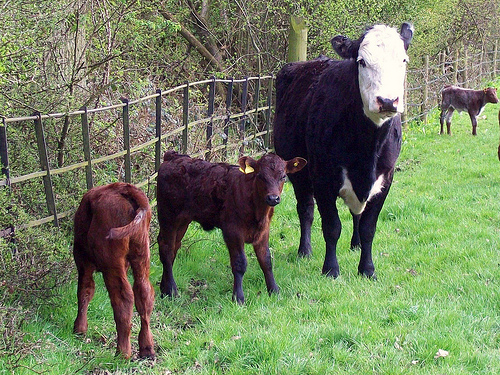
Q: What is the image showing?
A: It is showing a field.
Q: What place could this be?
A: It is a field.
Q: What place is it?
A: It is a field.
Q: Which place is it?
A: It is a field.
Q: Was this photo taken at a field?
A: Yes, it was taken in a field.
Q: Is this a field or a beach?
A: It is a field.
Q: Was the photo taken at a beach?
A: No, the picture was taken in a field.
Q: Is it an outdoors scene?
A: Yes, it is outdoors.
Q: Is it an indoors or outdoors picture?
A: It is outdoors.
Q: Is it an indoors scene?
A: No, it is outdoors.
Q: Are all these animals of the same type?
A: Yes, all the animals are cows.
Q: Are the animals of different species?
A: No, all the animals are cows.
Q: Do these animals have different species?
A: No, all the animals are cows.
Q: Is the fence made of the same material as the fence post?
A: Yes, both the fence and the fence post are made of wood.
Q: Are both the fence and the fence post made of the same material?
A: Yes, both the fence and the fence post are made of wood.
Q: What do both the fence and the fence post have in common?
A: The material, both the fence and the fence post are wooden.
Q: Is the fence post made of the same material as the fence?
A: Yes, both the fence post and the fence are made of wood.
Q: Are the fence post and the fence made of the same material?
A: Yes, both the fence post and the fence are made of wood.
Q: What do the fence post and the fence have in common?
A: The material, both the fence post and the fence are wooden.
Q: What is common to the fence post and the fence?
A: The material, both the fence post and the fence are wooden.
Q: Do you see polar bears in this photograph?
A: No, there are no polar bears.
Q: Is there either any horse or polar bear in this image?
A: No, there are no polar bears or horses.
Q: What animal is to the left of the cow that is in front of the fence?
A: The animal is a calf.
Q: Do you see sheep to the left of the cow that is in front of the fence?
A: No, there is a calf to the left of the cow.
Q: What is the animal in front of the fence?
A: The animal is a calf.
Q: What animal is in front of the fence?
A: The animal is a calf.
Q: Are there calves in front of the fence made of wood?
A: Yes, there is a calf in front of the fence.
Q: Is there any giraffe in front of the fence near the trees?
A: No, there is a calf in front of the fence.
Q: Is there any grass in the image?
A: Yes, there is grass.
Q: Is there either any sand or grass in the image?
A: Yes, there is grass.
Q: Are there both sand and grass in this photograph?
A: No, there is grass but no sand.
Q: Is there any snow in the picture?
A: No, there is no snow.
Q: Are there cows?
A: Yes, there is a cow.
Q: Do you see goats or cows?
A: Yes, there is a cow.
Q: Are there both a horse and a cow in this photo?
A: No, there is a cow but no horses.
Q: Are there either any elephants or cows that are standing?
A: Yes, the cow is standing.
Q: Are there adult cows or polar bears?
A: Yes, there is an adult cow.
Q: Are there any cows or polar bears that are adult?
A: Yes, the cow is adult.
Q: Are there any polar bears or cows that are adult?
A: Yes, the cow is adult.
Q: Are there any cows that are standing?
A: Yes, there is a cow that is standing.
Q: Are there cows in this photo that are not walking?
A: Yes, there is a cow that is standing.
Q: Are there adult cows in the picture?
A: Yes, there is an adult cow.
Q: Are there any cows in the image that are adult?
A: Yes, there is a cow that is adult.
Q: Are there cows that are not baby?
A: Yes, there is a adult cow.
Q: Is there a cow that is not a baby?
A: Yes, there is a adult cow.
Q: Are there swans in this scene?
A: No, there are no swans.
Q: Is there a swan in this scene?
A: No, there are no swans.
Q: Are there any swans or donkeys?
A: No, there are no swans or donkeys.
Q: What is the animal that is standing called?
A: The animal is a cow.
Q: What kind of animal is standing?
A: The animal is a cow.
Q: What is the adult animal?
A: The animal is a cow.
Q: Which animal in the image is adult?
A: The animal is a cow.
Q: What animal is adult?
A: The animal is a cow.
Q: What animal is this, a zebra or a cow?
A: This is a cow.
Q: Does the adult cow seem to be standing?
A: Yes, the cow is standing.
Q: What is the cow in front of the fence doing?
A: The cow is standing.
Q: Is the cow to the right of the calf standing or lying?
A: The cow is standing.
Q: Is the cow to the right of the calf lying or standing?
A: The cow is standing.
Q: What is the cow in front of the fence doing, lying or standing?
A: The cow is standing.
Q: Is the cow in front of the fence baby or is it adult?
A: The cow is adult.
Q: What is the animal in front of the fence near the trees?
A: The animal is a cow.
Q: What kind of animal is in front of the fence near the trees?
A: The animal is a cow.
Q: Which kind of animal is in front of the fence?
A: The animal is a cow.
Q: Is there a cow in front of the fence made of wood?
A: Yes, there is a cow in front of the fence.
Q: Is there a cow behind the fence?
A: No, the cow is in front of the fence.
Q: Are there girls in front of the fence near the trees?
A: No, there is a cow in front of the fence.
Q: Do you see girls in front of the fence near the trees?
A: No, there is a cow in front of the fence.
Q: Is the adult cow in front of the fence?
A: Yes, the cow is in front of the fence.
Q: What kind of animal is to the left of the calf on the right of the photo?
A: The animal is a cow.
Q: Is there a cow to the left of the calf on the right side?
A: Yes, there is a cow to the left of the calf.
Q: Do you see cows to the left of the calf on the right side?
A: Yes, there is a cow to the left of the calf.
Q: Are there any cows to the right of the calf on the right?
A: No, the cow is to the left of the calf.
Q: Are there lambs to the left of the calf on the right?
A: No, there is a cow to the left of the calf.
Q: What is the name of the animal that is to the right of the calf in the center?
A: The animal is a cow.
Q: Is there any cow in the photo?
A: Yes, there is a cow.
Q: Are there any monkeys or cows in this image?
A: Yes, there is a cow.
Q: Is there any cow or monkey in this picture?
A: Yes, there is a cow.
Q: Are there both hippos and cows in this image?
A: No, there is a cow but no hippos.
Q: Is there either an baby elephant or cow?
A: Yes, there is a baby cow.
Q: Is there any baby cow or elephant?
A: Yes, there is a baby cow.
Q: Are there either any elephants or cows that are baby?
A: Yes, the cow is a baby.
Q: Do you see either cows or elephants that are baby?
A: Yes, the cow is a baby.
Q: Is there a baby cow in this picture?
A: Yes, there is a baby cow.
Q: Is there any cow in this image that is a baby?
A: Yes, there is a cow that is a baby.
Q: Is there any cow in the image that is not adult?
A: Yes, there is an baby cow.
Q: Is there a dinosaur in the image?
A: No, there are no dinosaurs.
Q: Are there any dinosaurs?
A: No, there are no dinosaurs.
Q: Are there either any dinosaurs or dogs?
A: No, there are no dinosaurs or dogs.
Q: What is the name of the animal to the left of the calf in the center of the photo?
A: The animal is a cow.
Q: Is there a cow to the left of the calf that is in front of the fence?
A: Yes, there is a cow to the left of the calf.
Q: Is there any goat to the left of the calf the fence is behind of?
A: No, there is a cow to the left of the calf.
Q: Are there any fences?
A: Yes, there is a fence.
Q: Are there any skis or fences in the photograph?
A: Yes, there is a fence.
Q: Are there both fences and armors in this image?
A: No, there is a fence but no armors.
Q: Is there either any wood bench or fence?
A: Yes, there is a wood fence.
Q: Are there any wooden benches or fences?
A: Yes, there is a wood fence.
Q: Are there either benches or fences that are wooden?
A: Yes, the fence is wooden.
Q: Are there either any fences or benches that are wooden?
A: Yes, the fence is wooden.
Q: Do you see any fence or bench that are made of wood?
A: Yes, the fence is made of wood.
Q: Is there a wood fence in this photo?
A: Yes, there is a wood fence.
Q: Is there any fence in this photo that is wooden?
A: Yes, there is a fence that is wooden.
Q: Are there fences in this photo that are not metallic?
A: Yes, there is a wooden fence.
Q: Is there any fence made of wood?
A: Yes, there is a fence that is made of wood.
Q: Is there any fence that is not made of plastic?
A: Yes, there is a fence that is made of wood.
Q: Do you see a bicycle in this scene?
A: No, there are no bicycles.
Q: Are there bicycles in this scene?
A: No, there are no bicycles.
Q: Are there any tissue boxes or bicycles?
A: No, there are no bicycles or tissue boxes.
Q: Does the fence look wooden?
A: Yes, the fence is wooden.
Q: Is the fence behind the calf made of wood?
A: Yes, the fence is made of wood.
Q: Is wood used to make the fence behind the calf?
A: Yes, the fence is made of wood.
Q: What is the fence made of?
A: The fence is made of wood.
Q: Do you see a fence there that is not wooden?
A: No, there is a fence but it is wooden.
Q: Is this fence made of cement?
A: No, the fence is made of wood.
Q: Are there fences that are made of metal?
A: No, there is a fence but it is made of wood.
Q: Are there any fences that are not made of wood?
A: No, there is a fence but it is made of wood.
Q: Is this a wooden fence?
A: Yes, this is a wooden fence.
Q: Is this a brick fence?
A: No, this is a wooden fence.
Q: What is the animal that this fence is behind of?
A: The animal is a calf.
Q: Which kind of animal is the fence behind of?
A: The fence is behind the calf.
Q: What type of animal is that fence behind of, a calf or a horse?
A: The fence is behind a calf.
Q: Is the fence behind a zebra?
A: No, the fence is behind the calf.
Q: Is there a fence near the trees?
A: Yes, there is a fence near the trees.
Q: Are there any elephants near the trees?
A: No, there is a fence near the trees.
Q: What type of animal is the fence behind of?
A: The fence is behind the cow.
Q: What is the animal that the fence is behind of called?
A: The animal is a cow.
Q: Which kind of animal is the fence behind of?
A: The fence is behind the cow.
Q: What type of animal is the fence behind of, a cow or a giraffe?
A: The fence is behind a cow.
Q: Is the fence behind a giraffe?
A: No, the fence is behind the cow.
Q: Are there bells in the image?
A: No, there are no bells.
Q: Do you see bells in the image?
A: No, there are no bells.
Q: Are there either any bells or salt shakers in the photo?
A: No, there are no bells or salt shakers.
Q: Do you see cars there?
A: No, there are no cars.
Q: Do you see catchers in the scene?
A: No, there are no catchers.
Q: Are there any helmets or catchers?
A: No, there are no catchers or helmets.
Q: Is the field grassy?
A: Yes, the field is grassy.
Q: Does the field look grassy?
A: Yes, the field is grassy.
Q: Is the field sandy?
A: No, the field is grassy.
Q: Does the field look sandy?
A: No, the field is grassy.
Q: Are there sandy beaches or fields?
A: No, there is a field but it is grassy.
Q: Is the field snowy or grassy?
A: The field is grassy.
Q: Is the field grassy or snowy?
A: The field is grassy.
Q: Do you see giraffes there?
A: No, there are no giraffes.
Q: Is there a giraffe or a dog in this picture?
A: No, there are no giraffes or dogs.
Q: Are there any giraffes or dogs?
A: No, there are no giraffes or dogs.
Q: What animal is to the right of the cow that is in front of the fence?
A: The animal is a calf.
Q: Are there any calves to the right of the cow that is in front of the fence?
A: Yes, there is a calf to the right of the cow.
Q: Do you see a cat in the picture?
A: No, there are no cats.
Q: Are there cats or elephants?
A: No, there are no cats or elephants.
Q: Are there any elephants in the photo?
A: No, there are no elephants.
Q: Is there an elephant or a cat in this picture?
A: No, there are no elephants or cats.